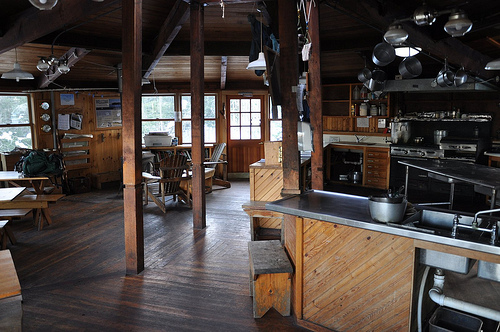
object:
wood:
[121, 0, 147, 276]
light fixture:
[392, 45, 424, 59]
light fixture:
[382, 0, 476, 48]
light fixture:
[0, 39, 35, 82]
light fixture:
[33, 54, 71, 84]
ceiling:
[0, 0, 498, 88]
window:
[0, 92, 36, 128]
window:
[139, 94, 179, 121]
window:
[177, 92, 218, 121]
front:
[0, 89, 271, 192]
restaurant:
[0, 0, 500, 330]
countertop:
[262, 188, 500, 249]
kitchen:
[264, 0, 500, 331]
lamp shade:
[1, 19, 35, 81]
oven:
[389, 143, 450, 198]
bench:
[246, 238, 295, 320]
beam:
[186, 0, 207, 231]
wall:
[28, 87, 122, 189]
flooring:
[0, 177, 317, 331]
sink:
[400, 209, 480, 238]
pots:
[437, 57, 454, 90]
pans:
[395, 43, 425, 79]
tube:
[428, 266, 500, 322]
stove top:
[391, 109, 489, 122]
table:
[394, 157, 500, 222]